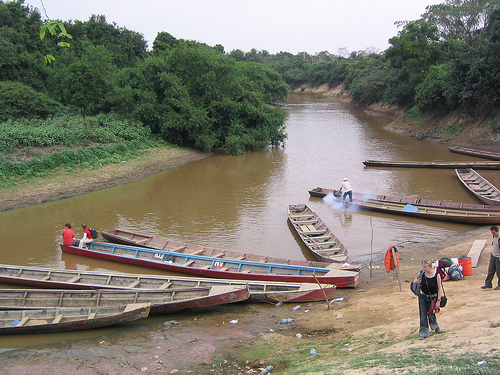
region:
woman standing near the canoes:
[410, 257, 446, 334]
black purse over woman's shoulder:
[435, 275, 447, 306]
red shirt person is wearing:
[61, 225, 74, 245]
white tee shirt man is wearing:
[340, 178, 350, 189]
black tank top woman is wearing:
[418, 272, 436, 293]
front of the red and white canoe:
[250, 281, 331, 306]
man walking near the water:
[485, 223, 498, 289]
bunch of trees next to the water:
[108, 42, 288, 154]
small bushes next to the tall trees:
[2, 111, 165, 187]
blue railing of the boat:
[89, 239, 329, 274]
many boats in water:
[34, 134, 494, 356]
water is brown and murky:
[168, 144, 299, 251]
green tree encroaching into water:
[102, 27, 300, 145]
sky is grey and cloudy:
[184, 1, 361, 56]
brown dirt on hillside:
[340, 108, 495, 182]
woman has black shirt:
[408, 273, 433, 301]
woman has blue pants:
[420, 284, 465, 334]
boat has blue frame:
[90, 237, 315, 285]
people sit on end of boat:
[51, 217, 133, 264]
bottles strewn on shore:
[208, 274, 419, 364]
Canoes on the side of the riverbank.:
[1, 55, 491, 360]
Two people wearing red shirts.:
[56, 220, 98, 251]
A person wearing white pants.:
[74, 221, 95, 251]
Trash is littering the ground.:
[111, 295, 385, 373]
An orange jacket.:
[385, 240, 407, 290]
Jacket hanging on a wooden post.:
[379, 241, 407, 296]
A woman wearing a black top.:
[409, 251, 452, 338]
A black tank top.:
[408, 268, 445, 301]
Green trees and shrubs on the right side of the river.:
[291, 33, 491, 159]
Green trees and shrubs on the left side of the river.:
[5, 10, 292, 175]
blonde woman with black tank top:
[412, 255, 449, 336]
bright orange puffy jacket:
[380, 247, 402, 287]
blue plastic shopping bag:
[308, 344, 318, 358]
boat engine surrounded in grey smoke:
[323, 181, 373, 212]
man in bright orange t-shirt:
[57, 216, 77, 250]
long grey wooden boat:
[282, 198, 347, 261]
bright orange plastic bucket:
[459, 254, 474, 276]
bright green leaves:
[35, 18, 70, 65]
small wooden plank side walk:
[465, 233, 486, 272]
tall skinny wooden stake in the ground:
[367, 213, 374, 282]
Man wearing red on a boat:
[60, 223, 78, 245]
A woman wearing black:
[413, 259, 443, 331]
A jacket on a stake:
[384, 243, 404, 290]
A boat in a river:
[287, 201, 348, 261]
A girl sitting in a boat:
[80, 223, 97, 248]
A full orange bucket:
[459, 255, 471, 275]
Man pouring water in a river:
[335, 176, 352, 203]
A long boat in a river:
[362, 156, 499, 168]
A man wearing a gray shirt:
[483, 226, 498, 289]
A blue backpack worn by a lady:
[87, 227, 97, 239]